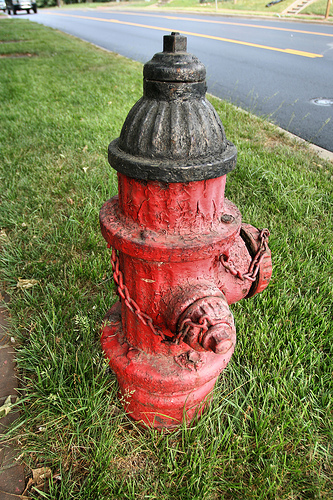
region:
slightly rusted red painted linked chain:
[107, 265, 159, 335]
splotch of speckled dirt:
[6, 461, 31, 496]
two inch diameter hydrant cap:
[241, 220, 276, 298]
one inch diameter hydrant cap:
[170, 288, 240, 361]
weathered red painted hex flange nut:
[205, 317, 234, 360]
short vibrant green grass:
[183, 421, 271, 497]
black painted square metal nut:
[152, 21, 193, 57]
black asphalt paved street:
[243, 38, 328, 123]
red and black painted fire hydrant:
[90, 29, 274, 431]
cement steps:
[276, 0, 311, 17]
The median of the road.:
[156, 8, 330, 55]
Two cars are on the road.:
[0, 0, 48, 19]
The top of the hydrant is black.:
[84, 18, 247, 221]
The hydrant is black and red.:
[76, 26, 273, 432]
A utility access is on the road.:
[294, 84, 329, 107]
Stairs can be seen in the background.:
[276, 0, 327, 17]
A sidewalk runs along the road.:
[77, 0, 330, 24]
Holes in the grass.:
[0, 44, 43, 68]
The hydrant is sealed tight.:
[158, 218, 298, 384]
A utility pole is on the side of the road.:
[319, 0, 331, 22]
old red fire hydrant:
[92, 153, 260, 437]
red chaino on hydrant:
[95, 254, 203, 357]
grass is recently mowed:
[61, 317, 325, 495]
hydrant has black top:
[110, 64, 247, 190]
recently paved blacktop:
[246, 57, 324, 193]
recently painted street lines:
[289, 48, 324, 67]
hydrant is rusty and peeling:
[79, 145, 248, 404]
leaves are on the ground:
[0, 276, 61, 498]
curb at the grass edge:
[219, 87, 326, 169]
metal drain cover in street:
[299, 78, 330, 115]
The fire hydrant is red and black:
[78, 40, 269, 438]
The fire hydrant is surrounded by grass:
[36, 134, 271, 476]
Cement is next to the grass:
[0, 313, 97, 495]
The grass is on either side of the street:
[99, 0, 289, 165]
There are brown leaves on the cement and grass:
[10, 278, 140, 493]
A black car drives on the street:
[4, 0, 57, 29]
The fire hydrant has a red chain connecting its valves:
[94, 190, 284, 380]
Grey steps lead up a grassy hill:
[281, 1, 317, 20]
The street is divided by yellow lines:
[99, 0, 318, 63]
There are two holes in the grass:
[2, 25, 47, 64]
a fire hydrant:
[87, 37, 269, 427]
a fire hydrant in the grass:
[90, 30, 273, 444]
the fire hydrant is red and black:
[84, 30, 279, 445]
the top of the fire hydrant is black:
[98, 26, 263, 194]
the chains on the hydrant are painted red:
[94, 177, 266, 426]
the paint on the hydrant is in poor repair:
[95, 41, 273, 446]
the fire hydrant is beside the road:
[87, 19, 331, 434]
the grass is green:
[3, 26, 318, 491]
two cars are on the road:
[1, 1, 40, 17]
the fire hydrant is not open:
[89, 39, 276, 440]